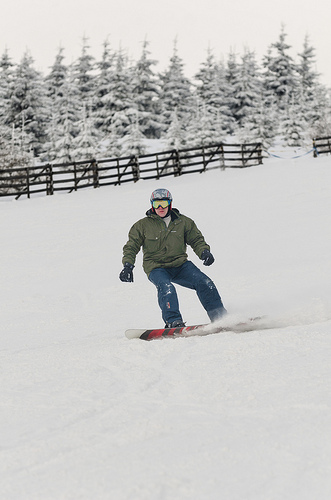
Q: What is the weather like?
A: It is cloudy.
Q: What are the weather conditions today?
A: It is cloudy.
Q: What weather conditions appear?
A: It is cloudy.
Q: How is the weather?
A: It is cloudy.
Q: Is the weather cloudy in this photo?
A: Yes, it is cloudy.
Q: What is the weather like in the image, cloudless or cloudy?
A: It is cloudy.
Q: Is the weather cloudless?
A: No, it is cloudy.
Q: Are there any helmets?
A: Yes, there is a helmet.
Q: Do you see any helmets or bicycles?
A: Yes, there is a helmet.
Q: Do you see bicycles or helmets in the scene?
A: Yes, there is a helmet.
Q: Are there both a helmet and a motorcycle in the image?
A: No, there is a helmet but no motorcycles.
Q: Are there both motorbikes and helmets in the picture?
A: No, there is a helmet but no motorcycles.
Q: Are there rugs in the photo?
A: No, there are no rugs.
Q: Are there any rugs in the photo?
A: No, there are no rugs.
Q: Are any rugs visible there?
A: No, there are no rugs.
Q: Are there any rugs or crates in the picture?
A: No, there are no rugs or crates.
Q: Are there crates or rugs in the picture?
A: No, there are no rugs or crates.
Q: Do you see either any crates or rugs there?
A: No, there are no rugs or crates.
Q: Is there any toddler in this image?
A: No, there are no toddlers.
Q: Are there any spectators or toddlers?
A: No, there are no toddlers or spectators.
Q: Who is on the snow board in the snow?
A: The man is on the snowboard.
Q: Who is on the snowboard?
A: The man is on the snowboard.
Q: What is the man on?
A: The man is on the snowboard.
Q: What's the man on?
A: The man is on the snowboard.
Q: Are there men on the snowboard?
A: Yes, there is a man on the snowboard.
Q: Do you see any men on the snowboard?
A: Yes, there is a man on the snowboard.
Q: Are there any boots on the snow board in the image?
A: No, there is a man on the snow board.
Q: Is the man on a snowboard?
A: Yes, the man is on a snowboard.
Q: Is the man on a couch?
A: No, the man is on a snowboard.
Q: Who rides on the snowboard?
A: The man rides on the snowboard.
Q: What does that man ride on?
A: The man rides on the snow board.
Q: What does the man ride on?
A: The man rides on the snow board.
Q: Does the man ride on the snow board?
A: Yes, the man rides on the snow board.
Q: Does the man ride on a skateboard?
A: No, the man rides on the snow board.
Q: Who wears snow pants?
A: The man wears snow pants.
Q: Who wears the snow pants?
A: The man wears snow pants.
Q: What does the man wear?
A: The man wears snowpants.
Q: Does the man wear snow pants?
A: Yes, the man wears snow pants.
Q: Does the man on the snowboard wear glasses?
A: No, the man wears snow pants.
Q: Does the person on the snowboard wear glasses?
A: No, the man wears snow pants.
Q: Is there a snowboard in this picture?
A: Yes, there is a snowboard.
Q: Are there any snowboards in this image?
A: Yes, there is a snowboard.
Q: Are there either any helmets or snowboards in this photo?
A: Yes, there is a snowboard.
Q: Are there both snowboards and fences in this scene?
A: Yes, there are both a snowboard and a fence.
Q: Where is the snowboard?
A: The snowboard is in the snow.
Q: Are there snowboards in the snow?
A: Yes, there is a snowboard in the snow.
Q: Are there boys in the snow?
A: No, there is a snowboard in the snow.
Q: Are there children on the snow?
A: No, there is a snowboard on the snow.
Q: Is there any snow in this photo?
A: Yes, there is snow.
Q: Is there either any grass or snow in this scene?
A: Yes, there is snow.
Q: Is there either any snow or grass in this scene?
A: Yes, there is snow.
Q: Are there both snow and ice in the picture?
A: No, there is snow but no ice.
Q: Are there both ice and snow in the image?
A: No, there is snow but no ice.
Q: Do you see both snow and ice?
A: No, there is snow but no ice.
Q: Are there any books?
A: No, there are no books.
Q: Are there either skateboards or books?
A: No, there are no books or skateboards.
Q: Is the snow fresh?
A: Yes, the snow is fresh.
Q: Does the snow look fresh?
A: Yes, the snow is fresh.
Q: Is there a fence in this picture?
A: Yes, there is a fence.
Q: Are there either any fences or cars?
A: Yes, there is a fence.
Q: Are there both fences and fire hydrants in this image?
A: No, there is a fence but no fire hydrants.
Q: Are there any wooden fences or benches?
A: Yes, there is a wood fence.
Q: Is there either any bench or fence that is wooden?
A: Yes, the fence is wooden.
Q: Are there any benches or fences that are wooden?
A: Yes, the fence is wooden.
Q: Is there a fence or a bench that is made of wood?
A: Yes, the fence is made of wood.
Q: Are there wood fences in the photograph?
A: Yes, there is a wood fence.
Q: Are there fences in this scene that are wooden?
A: Yes, there is a fence that is wooden.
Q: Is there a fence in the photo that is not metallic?
A: Yes, there is a wooden fence.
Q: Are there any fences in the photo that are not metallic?
A: Yes, there is a wooden fence.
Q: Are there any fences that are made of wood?
A: Yes, there is a fence that is made of wood.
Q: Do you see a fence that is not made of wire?
A: Yes, there is a fence that is made of wood.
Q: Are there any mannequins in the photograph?
A: No, there are no mannequins.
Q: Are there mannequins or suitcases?
A: No, there are no mannequins or suitcases.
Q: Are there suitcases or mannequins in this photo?
A: No, there are no mannequins or suitcases.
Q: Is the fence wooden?
A: Yes, the fence is wooden.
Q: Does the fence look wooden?
A: Yes, the fence is wooden.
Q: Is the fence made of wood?
A: Yes, the fence is made of wood.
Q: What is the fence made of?
A: The fence is made of wood.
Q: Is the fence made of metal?
A: No, the fence is made of wood.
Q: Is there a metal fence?
A: No, there is a fence but it is made of wood.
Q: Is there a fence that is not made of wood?
A: No, there is a fence but it is made of wood.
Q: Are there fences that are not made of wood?
A: No, there is a fence but it is made of wood.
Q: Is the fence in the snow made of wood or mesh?
A: The fence is made of wood.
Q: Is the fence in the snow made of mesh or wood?
A: The fence is made of wood.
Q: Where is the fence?
A: The fence is in the snow.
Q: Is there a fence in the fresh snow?
A: Yes, there is a fence in the snow.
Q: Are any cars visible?
A: No, there are no cars.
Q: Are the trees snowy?
A: Yes, the trees are snowy.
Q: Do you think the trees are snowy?
A: Yes, the trees are snowy.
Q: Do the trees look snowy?
A: Yes, the trees are snowy.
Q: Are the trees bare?
A: No, the trees are snowy.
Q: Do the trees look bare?
A: No, the trees are snowy.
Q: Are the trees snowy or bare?
A: The trees are snowy.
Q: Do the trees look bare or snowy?
A: The trees are snowy.